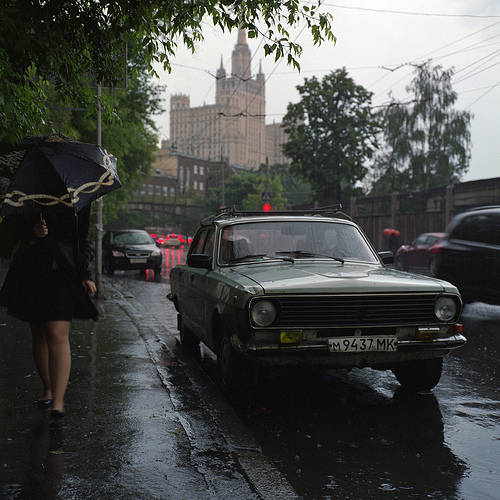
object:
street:
[337, 435, 491, 484]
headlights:
[251, 300, 277, 327]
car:
[165, 203, 468, 396]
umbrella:
[0, 133, 123, 218]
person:
[388, 233, 400, 254]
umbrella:
[383, 228, 401, 237]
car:
[102, 229, 163, 276]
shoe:
[38, 399, 53, 407]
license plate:
[327, 335, 398, 353]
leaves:
[310, 87, 353, 125]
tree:
[281, 65, 386, 202]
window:
[218, 222, 377, 265]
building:
[122, 23, 306, 220]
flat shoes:
[50, 407, 67, 421]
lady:
[0, 201, 99, 418]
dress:
[0, 200, 99, 322]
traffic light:
[263, 203, 271, 211]